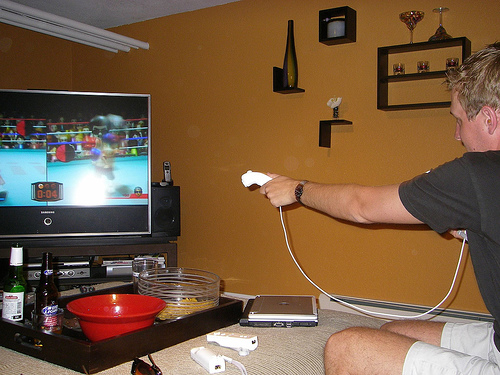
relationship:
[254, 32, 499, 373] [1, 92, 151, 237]
man playing game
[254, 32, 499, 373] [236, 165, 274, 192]
man holding controller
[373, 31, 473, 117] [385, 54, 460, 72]
shelf with glasses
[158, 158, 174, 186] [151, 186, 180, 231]
phone sitting on speaker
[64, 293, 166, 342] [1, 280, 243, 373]
red bowl in tray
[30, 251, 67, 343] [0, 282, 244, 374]
bottle in drawer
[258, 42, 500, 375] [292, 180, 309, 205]
man wearing watch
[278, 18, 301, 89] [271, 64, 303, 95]
vase on shelf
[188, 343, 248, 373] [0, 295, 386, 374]
controller on bed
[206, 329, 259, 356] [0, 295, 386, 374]
controller on bed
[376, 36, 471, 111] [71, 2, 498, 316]
shelf on wall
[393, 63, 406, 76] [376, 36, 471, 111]
glasses on shelf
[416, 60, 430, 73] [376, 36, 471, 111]
glasses on shelf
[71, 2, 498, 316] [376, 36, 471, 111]
wall with shelf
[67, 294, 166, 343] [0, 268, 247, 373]
red bowl in drawer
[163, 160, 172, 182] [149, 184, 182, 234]
phone atop speaker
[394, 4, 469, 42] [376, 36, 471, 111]
glasses on a shelf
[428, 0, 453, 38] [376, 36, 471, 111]
glasses on a shelf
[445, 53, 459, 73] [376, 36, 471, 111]
glasses on a shelf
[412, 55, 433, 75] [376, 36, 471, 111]
glasses on a shelf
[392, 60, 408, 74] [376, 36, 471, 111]
glasses on a shelf